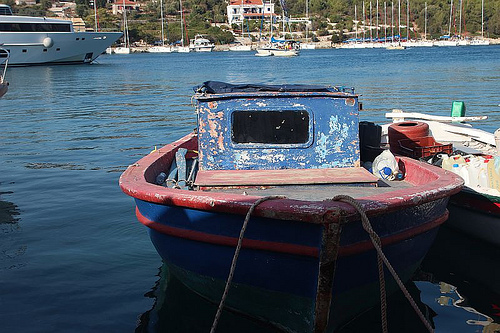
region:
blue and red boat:
[122, 87, 480, 319]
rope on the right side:
[312, 186, 447, 331]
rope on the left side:
[192, 191, 297, 331]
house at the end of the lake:
[222, 1, 283, 37]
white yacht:
[0, 6, 130, 75]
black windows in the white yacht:
[0, 17, 76, 35]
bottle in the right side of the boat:
[361, 140, 401, 191]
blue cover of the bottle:
[377, 163, 390, 181]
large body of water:
[0, 36, 497, 331]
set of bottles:
[437, 143, 497, 193]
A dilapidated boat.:
[112, 60, 468, 321]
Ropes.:
[195, 187, 431, 327]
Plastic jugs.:
[440, 140, 495, 187]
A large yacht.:
[0, 0, 141, 75]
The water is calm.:
[2, 45, 492, 175]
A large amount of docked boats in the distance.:
[130, 15, 495, 75]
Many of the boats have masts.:
[142, 0, 492, 66]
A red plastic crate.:
[390, 130, 455, 167]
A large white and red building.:
[220, 0, 280, 35]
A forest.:
[303, 2, 496, 39]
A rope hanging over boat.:
[92, 186, 397, 331]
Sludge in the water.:
[412, 242, 499, 328]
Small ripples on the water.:
[1, 103, 114, 200]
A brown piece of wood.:
[184, 152, 374, 195]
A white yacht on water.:
[0, 0, 122, 89]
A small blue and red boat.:
[169, 65, 359, 307]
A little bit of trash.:
[347, 141, 422, 191]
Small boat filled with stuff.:
[418, 70, 498, 271]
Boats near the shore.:
[121, 20, 483, 76]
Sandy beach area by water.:
[166, 30, 493, 86]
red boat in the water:
[122, 63, 467, 318]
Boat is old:
[119, 74, 471, 322]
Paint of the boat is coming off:
[111, 64, 477, 331]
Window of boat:
[224, 99, 321, 153]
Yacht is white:
[0, 2, 130, 71]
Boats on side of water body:
[125, 31, 305, 60]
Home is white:
[222, 1, 279, 33]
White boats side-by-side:
[334, 0, 496, 50]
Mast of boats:
[347, 0, 489, 38]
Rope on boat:
[204, 181, 436, 331]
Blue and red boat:
[117, 75, 464, 332]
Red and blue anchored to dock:
[117, 76, 464, 331]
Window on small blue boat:
[222, 106, 316, 146]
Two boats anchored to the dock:
[117, 78, 498, 330]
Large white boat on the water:
[0, 2, 124, 67]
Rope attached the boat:
[205, 194, 443, 331]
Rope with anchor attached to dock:
[206, 195, 432, 327]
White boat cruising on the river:
[1, 2, 128, 70]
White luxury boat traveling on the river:
[0, 2, 497, 77]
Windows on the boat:
[0, 21, 77, 32]